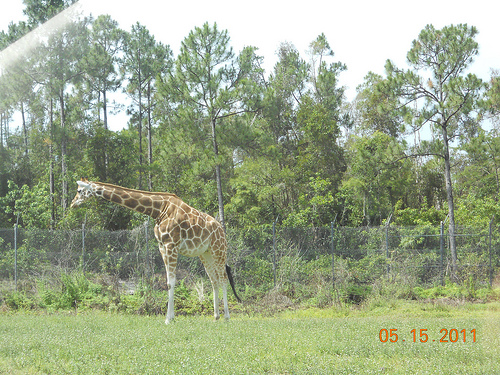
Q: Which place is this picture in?
A: It is at the zoo.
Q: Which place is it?
A: It is a zoo.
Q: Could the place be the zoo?
A: Yes, it is the zoo.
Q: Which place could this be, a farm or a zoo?
A: It is a zoo.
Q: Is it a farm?
A: No, it is a zoo.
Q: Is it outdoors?
A: Yes, it is outdoors.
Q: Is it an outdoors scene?
A: Yes, it is outdoors.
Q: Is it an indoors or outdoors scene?
A: It is outdoors.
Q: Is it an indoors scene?
A: No, it is outdoors.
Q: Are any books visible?
A: No, there are no books.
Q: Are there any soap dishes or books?
A: No, there are no books or soap dishes.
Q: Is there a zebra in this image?
A: No, there are no zebras.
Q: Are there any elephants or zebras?
A: No, there are no zebras or elephants.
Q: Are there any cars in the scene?
A: No, there are no cars.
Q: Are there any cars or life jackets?
A: No, there are no cars or life jackets.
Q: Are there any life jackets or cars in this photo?
A: No, there are no cars or life jackets.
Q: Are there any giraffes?
A: Yes, there is a giraffe.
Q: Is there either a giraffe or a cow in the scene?
A: Yes, there is a giraffe.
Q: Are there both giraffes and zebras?
A: No, there is a giraffe but no zebras.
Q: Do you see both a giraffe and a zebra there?
A: No, there is a giraffe but no zebras.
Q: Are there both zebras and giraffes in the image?
A: No, there is a giraffe but no zebras.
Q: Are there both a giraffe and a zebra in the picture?
A: No, there is a giraffe but no zebras.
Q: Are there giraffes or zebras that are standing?
A: Yes, the giraffe is standing.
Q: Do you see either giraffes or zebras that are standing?
A: Yes, the giraffe is standing.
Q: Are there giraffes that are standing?
A: Yes, there is a giraffe that is standing.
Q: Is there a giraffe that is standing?
A: Yes, there is a giraffe that is standing.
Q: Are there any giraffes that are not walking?
A: Yes, there is a giraffe that is standing.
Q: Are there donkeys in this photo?
A: No, there are no donkeys.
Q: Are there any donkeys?
A: No, there are no donkeys.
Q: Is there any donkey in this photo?
A: No, there are no donkeys.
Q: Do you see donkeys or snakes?
A: No, there are no donkeys or snakes.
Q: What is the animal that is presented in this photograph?
A: The animal is a giraffe.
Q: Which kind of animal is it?
A: The animal is a giraffe.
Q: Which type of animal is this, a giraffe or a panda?
A: That is a giraffe.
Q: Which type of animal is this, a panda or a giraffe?
A: That is a giraffe.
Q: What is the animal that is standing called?
A: The animal is a giraffe.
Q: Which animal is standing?
A: The animal is a giraffe.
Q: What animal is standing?
A: The animal is a giraffe.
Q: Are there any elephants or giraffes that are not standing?
A: No, there is a giraffe but it is standing.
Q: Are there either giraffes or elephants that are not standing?
A: No, there is a giraffe but it is standing.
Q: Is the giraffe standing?
A: Yes, the giraffe is standing.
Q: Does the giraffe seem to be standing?
A: Yes, the giraffe is standing.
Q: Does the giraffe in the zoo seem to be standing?
A: Yes, the giraffe is standing.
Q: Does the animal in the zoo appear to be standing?
A: Yes, the giraffe is standing.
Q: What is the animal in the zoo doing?
A: The giraffe is standing.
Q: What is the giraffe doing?
A: The giraffe is standing.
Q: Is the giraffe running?
A: No, the giraffe is standing.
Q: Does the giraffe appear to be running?
A: No, the giraffe is standing.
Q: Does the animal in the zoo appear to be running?
A: No, the giraffe is standing.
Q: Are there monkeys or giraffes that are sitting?
A: No, there is a giraffe but it is standing.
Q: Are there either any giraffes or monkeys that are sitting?
A: No, there is a giraffe but it is standing.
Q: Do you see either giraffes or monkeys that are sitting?
A: No, there is a giraffe but it is standing.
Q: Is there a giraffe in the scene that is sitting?
A: No, there is a giraffe but it is standing.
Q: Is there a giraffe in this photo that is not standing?
A: No, there is a giraffe but it is standing.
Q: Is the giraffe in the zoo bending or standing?
A: The giraffe is standing.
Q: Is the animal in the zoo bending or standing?
A: The giraffe is standing.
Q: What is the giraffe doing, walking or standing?
A: The giraffe is standing.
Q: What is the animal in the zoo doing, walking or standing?
A: The giraffe is standing.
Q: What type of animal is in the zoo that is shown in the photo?
A: The animal is a giraffe.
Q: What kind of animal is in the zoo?
A: The animal is a giraffe.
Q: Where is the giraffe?
A: The giraffe is in the zoo.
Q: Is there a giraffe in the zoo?
A: Yes, there is a giraffe in the zoo.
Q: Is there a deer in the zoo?
A: No, there is a giraffe in the zoo.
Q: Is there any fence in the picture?
A: Yes, there is a fence.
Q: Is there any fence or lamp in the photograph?
A: Yes, there is a fence.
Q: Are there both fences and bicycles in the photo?
A: No, there is a fence but no bicycles.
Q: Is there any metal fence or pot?
A: Yes, there is a metal fence.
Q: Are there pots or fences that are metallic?
A: Yes, the fence is metallic.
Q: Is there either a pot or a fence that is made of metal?
A: Yes, the fence is made of metal.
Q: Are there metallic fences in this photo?
A: Yes, there is a metal fence.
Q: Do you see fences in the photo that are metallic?
A: Yes, there is a fence that is metallic.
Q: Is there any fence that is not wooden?
A: Yes, there is a metallic fence.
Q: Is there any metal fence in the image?
A: Yes, there is a fence that is made of metal.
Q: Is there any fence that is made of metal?
A: Yes, there is a fence that is made of metal.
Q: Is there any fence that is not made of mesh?
A: Yes, there is a fence that is made of metal.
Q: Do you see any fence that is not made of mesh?
A: Yes, there is a fence that is made of metal.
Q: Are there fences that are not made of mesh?
A: Yes, there is a fence that is made of metal.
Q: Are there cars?
A: No, there are no cars.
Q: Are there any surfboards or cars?
A: No, there are no cars or surfboards.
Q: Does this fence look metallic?
A: Yes, the fence is metallic.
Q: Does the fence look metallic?
A: Yes, the fence is metallic.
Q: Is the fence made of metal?
A: Yes, the fence is made of metal.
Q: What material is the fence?
A: The fence is made of metal.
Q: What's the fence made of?
A: The fence is made of metal.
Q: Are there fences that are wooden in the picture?
A: No, there is a fence but it is metallic.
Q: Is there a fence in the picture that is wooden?
A: No, there is a fence but it is metallic.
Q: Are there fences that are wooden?
A: No, there is a fence but it is metallic.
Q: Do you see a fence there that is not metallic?
A: No, there is a fence but it is metallic.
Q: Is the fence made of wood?
A: No, the fence is made of metal.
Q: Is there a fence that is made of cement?
A: No, there is a fence but it is made of metal.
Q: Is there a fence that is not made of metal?
A: No, there is a fence but it is made of metal.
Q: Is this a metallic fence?
A: Yes, this is a metallic fence.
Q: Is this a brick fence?
A: No, this is a metallic fence.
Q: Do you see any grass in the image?
A: Yes, there is grass.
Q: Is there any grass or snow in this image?
A: Yes, there is grass.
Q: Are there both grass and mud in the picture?
A: No, there is grass but no mud.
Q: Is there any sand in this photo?
A: No, there is no sand.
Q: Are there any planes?
A: No, there are no planes.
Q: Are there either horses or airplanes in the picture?
A: No, there are no airplanes or horses.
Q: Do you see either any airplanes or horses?
A: No, there are no airplanes or horses.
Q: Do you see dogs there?
A: No, there are no dogs.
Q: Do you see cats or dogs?
A: No, there are no dogs or cats.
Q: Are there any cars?
A: No, there are no cars.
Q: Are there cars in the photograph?
A: No, there are no cars.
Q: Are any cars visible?
A: No, there are no cars.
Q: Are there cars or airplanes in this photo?
A: No, there are no cars or airplanes.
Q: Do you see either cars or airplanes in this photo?
A: No, there are no cars or airplanes.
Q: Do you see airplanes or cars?
A: No, there are no cars or airplanes.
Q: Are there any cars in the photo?
A: No, there are no cars.